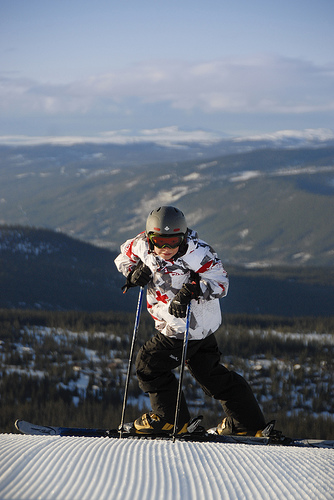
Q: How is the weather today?
A: It is cloudy.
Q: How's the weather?
A: It is cloudy.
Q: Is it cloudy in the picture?
A: Yes, it is cloudy.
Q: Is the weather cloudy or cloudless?
A: It is cloudy.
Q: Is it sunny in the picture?
A: No, it is cloudy.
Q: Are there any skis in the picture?
A: Yes, there are skis.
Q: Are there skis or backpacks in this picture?
A: Yes, there are skis.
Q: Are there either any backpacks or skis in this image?
A: Yes, there are skis.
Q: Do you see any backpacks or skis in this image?
A: Yes, there are skis.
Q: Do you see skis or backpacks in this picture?
A: Yes, there are skis.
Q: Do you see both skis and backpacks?
A: No, there are skis but no backpacks.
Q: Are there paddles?
A: No, there are no paddles.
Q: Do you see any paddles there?
A: No, there are no paddles.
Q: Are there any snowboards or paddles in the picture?
A: No, there are no paddles or snowboards.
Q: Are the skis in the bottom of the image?
A: Yes, the skis are in the bottom of the image.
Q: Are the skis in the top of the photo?
A: No, the skis are in the bottom of the image.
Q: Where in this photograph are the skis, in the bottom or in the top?
A: The skis are in the bottom of the image.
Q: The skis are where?
A: The skis are in the snow.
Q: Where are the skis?
A: The skis are in the snow.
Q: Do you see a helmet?
A: Yes, there is a helmet.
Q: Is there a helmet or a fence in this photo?
A: Yes, there is a helmet.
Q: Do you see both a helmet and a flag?
A: No, there is a helmet but no flags.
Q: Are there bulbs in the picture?
A: No, there are no bulbs.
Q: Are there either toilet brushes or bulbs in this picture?
A: No, there are no bulbs or toilet brushes.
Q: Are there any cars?
A: No, there are no cars.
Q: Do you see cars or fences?
A: No, there are no cars or fences.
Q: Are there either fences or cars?
A: No, there are no cars or fences.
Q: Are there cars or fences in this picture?
A: No, there are no cars or fences.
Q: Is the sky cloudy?
A: Yes, the sky is cloudy.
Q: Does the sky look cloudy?
A: Yes, the sky is cloudy.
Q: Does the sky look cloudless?
A: No, the sky is cloudy.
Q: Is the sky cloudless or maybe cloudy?
A: The sky is cloudy.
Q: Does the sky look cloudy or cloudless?
A: The sky is cloudy.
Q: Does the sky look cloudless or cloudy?
A: The sky is cloudy.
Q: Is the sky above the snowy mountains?
A: Yes, the sky is above the mountains.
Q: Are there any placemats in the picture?
A: No, there are no placemats.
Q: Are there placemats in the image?
A: No, there are no placemats.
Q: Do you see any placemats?
A: No, there are no placemats.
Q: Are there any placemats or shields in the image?
A: No, there are no placemats or shields.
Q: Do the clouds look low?
A: Yes, the clouds are low.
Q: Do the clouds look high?
A: No, the clouds are low.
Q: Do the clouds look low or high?
A: The clouds are low.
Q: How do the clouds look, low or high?
A: The clouds are low.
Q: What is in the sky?
A: The clouds are in the sky.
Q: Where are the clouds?
A: The clouds are in the sky.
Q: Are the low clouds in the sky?
A: Yes, the clouds are in the sky.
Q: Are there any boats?
A: No, there are no boats.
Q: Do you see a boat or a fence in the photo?
A: No, there are no boats or fences.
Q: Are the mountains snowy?
A: Yes, the mountains are snowy.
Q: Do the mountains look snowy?
A: Yes, the mountains are snowy.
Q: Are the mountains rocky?
A: No, the mountains are snowy.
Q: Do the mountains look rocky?
A: No, the mountains are snowy.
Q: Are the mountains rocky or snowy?
A: The mountains are snowy.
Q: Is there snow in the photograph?
A: Yes, there is snow.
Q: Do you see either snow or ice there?
A: Yes, there is snow.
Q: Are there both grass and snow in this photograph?
A: No, there is snow but no grass.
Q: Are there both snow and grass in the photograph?
A: No, there is snow but no grass.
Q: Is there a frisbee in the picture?
A: No, there are no frisbees.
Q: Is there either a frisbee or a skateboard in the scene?
A: No, there are no frisbees or skateboards.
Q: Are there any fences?
A: No, there are no fences.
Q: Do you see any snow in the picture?
A: Yes, there is snow.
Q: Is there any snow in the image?
A: Yes, there is snow.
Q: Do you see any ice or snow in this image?
A: Yes, there is snow.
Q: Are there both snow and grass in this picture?
A: No, there is snow but no grass.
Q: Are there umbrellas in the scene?
A: No, there are no umbrellas.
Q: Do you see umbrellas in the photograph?
A: No, there are no umbrellas.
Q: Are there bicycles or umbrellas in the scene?
A: No, there are no umbrellas or bicycles.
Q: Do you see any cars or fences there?
A: No, there are no fences or cars.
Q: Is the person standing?
A: Yes, the person is standing.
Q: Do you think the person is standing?
A: Yes, the person is standing.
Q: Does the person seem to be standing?
A: Yes, the person is standing.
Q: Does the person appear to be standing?
A: Yes, the person is standing.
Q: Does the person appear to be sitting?
A: No, the person is standing.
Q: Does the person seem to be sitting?
A: No, the person is standing.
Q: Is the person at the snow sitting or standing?
A: The person is standing.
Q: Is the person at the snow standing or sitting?
A: The person is standing.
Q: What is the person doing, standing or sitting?
A: The person is standing.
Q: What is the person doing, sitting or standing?
A: The person is standing.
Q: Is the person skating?
A: Yes, the person is skating.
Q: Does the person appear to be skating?
A: Yes, the person is skating.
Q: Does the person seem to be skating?
A: Yes, the person is skating.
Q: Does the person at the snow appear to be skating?
A: Yes, the person is skating.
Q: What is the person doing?
A: The person is skating.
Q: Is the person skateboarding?
A: No, the person is skating.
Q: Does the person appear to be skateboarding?
A: No, the person is skating.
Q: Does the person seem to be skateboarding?
A: No, the person is skating.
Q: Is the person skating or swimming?
A: The person is skating.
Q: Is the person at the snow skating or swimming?
A: The person is skating.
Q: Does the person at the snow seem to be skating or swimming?
A: The person is skating.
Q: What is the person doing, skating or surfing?
A: The person is skating.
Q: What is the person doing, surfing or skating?
A: The person is skating.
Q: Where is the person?
A: The person is at the snow.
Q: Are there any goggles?
A: Yes, there are goggles.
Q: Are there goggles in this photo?
A: Yes, there are goggles.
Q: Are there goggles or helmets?
A: Yes, there are goggles.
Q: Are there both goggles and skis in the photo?
A: Yes, there are both goggles and a ski.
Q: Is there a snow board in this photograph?
A: No, there are no snowboards.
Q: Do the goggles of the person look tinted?
A: Yes, the goggles are tinted.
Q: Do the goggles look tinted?
A: Yes, the goggles are tinted.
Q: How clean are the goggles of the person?
A: The goggles are tinted.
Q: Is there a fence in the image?
A: No, there are no fences.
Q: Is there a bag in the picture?
A: No, there are no bags.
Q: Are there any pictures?
A: No, there are no pictures.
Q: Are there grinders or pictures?
A: No, there are no pictures or grinders.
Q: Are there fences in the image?
A: No, there are no fences.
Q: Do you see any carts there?
A: No, there are no carts.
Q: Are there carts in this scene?
A: No, there are no carts.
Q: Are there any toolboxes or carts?
A: No, there are no carts or toolboxes.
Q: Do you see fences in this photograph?
A: No, there are no fences.